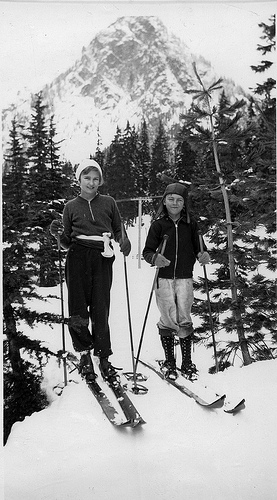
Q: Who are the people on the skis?
A: A young woman and young man.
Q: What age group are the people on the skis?
A: Two kids.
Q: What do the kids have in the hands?
A: Ski poles.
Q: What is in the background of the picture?
A: Tall evergreen trees.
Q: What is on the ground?
A: Snow.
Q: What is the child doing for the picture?
A: Posing.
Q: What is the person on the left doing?
A: Posing.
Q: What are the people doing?
A: Skiing.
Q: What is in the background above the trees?
A: Snow covered mountain.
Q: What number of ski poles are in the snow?
A: Four.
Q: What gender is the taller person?
A: Female.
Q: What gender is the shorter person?
A: Male.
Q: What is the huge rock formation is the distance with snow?
A: Mountain.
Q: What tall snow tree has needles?
A: Evergreen.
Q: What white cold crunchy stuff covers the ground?
A: Snow.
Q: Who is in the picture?
A: Women.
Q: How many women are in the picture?
A: Two.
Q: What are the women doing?
A: Skiing.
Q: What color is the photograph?
A: Black and white.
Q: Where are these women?
A: In the mountains.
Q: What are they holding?
A: Ski poles.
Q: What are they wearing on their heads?
A: Hats.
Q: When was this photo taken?
A: During the day.